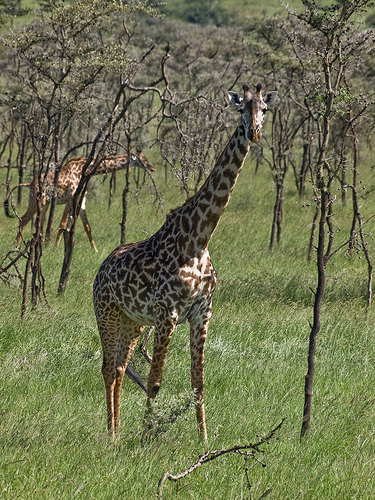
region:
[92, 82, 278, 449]
The giraffe is staring at the camera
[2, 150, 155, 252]
The giraffe is walking through the scrub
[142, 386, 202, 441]
A bush between the nearer giraffe's legs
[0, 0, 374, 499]
A grassy field dotted by trees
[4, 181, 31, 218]
The far giraffe's tail is held up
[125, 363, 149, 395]
The near giraffe's tail is relaxed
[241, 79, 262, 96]
Horns on a giraffe's head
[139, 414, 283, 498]
A branch lying in the grass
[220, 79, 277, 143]
A head on a giraffe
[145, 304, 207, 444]
Front legs on a giraffe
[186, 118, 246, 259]
A long neck on a giraffe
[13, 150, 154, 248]
A giraffe walking across a field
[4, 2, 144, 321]
A tall tree in the grass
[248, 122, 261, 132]
Nostrils on a giraffe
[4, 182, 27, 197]
A tail on a giraffe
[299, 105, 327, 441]
Thin trunk on a tree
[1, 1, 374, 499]
thin trees in tall green grass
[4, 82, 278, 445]
tow giraffes facing different directions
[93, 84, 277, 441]
front of standing giraffe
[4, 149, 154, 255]
walking giraffe with tilted neck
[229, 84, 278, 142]
giraffe head with two knobs on top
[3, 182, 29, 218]
tail with black hair on end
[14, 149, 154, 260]
giraffe with feet obstructed by grass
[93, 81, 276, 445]
giraffe with light reflection on chest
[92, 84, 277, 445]
brown spots on giraffe body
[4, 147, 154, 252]
giraffe with mane on neck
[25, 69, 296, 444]
two giraffes in a grass pasture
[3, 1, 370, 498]
trees in the grass pasture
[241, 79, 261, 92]
horns on the giraffe's head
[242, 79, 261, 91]
black tips of giraffe's horns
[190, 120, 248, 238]
spotted neck of the giraffe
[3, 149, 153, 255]
giraffe walking through the trees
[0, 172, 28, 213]
tail of the giraffe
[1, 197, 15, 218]
black hair on the giraffe's tail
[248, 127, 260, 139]
brown nose and mouth of the giraffe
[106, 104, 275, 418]
tall giraffe in grass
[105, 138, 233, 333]
brown and white spots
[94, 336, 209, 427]
giraffe has brown legs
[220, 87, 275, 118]
giraffe has white ears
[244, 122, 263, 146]
giraffe has brown nose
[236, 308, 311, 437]
grass is long and green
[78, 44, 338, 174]
bare trees around giraffe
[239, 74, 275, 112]
giraffe has brown ossicles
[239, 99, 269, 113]
giraffe has black eyes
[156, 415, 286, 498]
A twig in the grass